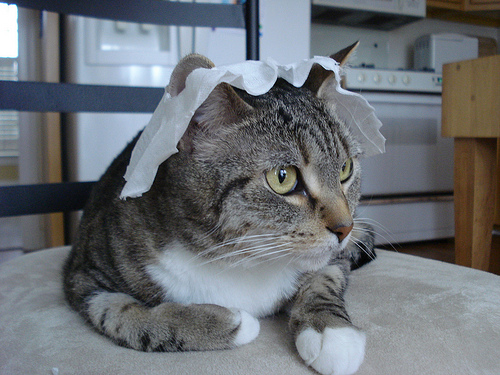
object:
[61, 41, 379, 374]
cat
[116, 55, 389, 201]
tissue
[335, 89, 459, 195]
oven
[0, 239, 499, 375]
seat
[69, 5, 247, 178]
refrigerator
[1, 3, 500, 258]
kitchen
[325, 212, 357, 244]
nose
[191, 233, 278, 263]
whiskers